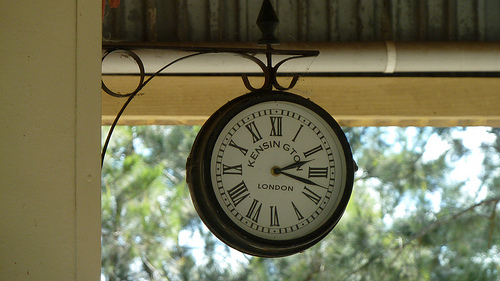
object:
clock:
[183, 90, 362, 260]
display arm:
[99, 42, 319, 173]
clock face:
[205, 99, 347, 241]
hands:
[272, 155, 327, 190]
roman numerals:
[223, 115, 330, 226]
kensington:
[245, 142, 305, 169]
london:
[256, 179, 291, 192]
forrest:
[99, 115, 495, 262]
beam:
[100, 67, 499, 132]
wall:
[3, 1, 106, 279]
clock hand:
[278, 156, 314, 171]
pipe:
[91, 41, 499, 76]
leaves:
[116, 160, 159, 219]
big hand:
[165, 106, 390, 241]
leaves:
[102, 126, 494, 279]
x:
[228, 138, 250, 161]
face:
[211, 102, 345, 242]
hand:
[269, 151, 314, 176]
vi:
[266, 202, 286, 234]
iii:
[302, 162, 331, 183]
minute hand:
[273, 170, 316, 186]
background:
[107, 121, 498, 225]